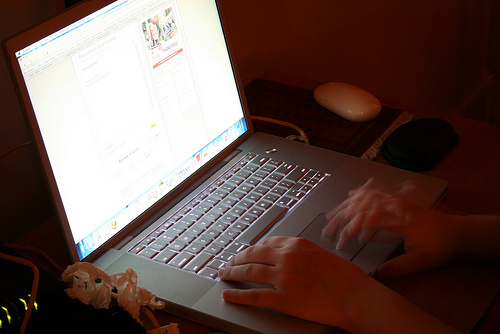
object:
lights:
[0, 290, 45, 331]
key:
[254, 176, 263, 186]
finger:
[256, 235, 298, 249]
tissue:
[58, 261, 114, 311]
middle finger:
[223, 243, 285, 266]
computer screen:
[14, 0, 247, 261]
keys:
[264, 158, 281, 165]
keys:
[281, 162, 310, 184]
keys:
[273, 193, 290, 208]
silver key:
[167, 240, 189, 252]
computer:
[0, 0, 452, 333]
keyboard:
[126, 150, 325, 282]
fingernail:
[221, 289, 231, 299]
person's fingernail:
[222, 289, 232, 296]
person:
[216, 179, 498, 333]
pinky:
[219, 288, 281, 310]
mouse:
[295, 212, 373, 264]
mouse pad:
[286, 212, 379, 264]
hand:
[318, 187, 458, 282]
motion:
[320, 170, 448, 274]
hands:
[214, 234, 379, 325]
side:
[60, 258, 258, 333]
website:
[15, 0, 247, 265]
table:
[0, 80, 498, 333]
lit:
[0, 1, 450, 334]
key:
[211, 233, 236, 246]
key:
[167, 240, 190, 250]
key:
[136, 245, 162, 258]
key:
[166, 250, 195, 269]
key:
[184, 242, 204, 254]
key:
[202, 241, 225, 254]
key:
[182, 247, 213, 272]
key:
[259, 177, 279, 192]